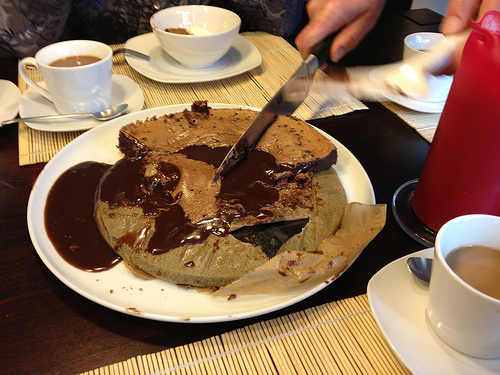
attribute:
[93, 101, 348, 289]
cake — large, chocolate, gooey, hot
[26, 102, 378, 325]
plate — white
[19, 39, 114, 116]
cup — small, white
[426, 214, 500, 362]
cup — white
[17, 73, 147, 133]
saucer — white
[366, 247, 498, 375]
saucer — white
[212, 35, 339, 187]
knife — large, silver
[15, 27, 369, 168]
placemat — wicker, thin, wood, beige, bamboo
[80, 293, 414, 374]
placemat — wicker, wood, thin, beige, bamboo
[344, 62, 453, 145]
placemat — wicker, thin, wood, beige, bamboo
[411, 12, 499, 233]
candle — red, tall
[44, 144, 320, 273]
chocolate — melted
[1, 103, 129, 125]
spoon — small, silver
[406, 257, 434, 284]
spoon — small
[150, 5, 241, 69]
bowl — round, white, small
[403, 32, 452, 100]
cup — small, white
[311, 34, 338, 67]
handle — black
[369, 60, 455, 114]
saucer — white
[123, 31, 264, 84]
saucer — white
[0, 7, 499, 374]
table — brown